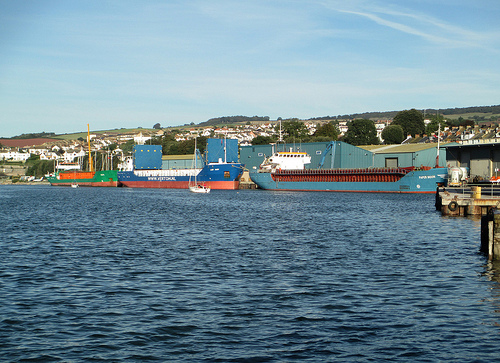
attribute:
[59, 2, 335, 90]
sky — blue, cloudy, light blue, overcast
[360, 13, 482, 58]
clouds — white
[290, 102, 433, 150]
trees — in background, green, large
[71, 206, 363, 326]
water — in fore, rippled, dark blue, blue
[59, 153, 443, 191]
boats — blue, docked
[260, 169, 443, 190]
boat — blue, red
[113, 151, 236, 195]
boat — red, white, blue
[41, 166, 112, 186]
boat — green, short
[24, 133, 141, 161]
houses — white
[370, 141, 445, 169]
buildings — blue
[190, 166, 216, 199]
boat — small, white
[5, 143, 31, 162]
building — white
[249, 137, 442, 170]
building — blue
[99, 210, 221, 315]
waves — blue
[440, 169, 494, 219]
dock — rusty